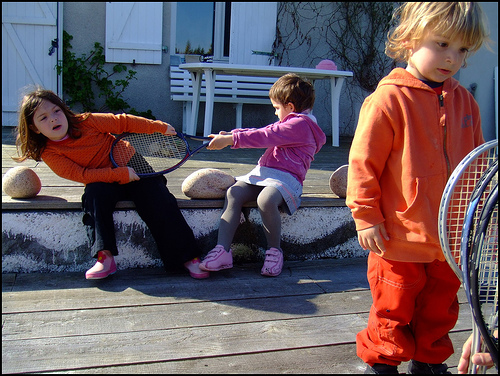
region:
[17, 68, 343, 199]
Two girls fighting over a tennis racquet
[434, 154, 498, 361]
Three tennis rackets together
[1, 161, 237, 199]
Stones spaced out on the deck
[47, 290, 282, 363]
A wooden plank walkway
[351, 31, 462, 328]
A boy in orange jacket and pants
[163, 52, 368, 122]
A white table and bench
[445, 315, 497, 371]
A hand holding a tennis racquet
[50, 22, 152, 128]
A vine growing alongside the house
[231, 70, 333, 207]
A girl with short hair in a pink jacket and skirt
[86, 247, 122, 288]
A red flower on a pink boot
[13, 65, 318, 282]
two girls fighting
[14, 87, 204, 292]
a girl in pink boots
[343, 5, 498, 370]
a boy with blonde hair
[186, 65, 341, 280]
a girl in pink sports shoes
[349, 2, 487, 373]
a boy in orange gear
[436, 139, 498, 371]
badminton rackets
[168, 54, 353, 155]
a white bench at the background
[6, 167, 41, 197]
a round stone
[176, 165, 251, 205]
a round stone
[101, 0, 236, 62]
a window at the background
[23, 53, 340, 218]
Two kids fighting over racket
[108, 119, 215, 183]
Blue and red tennis racket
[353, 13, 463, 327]
Kid wearing orange clothing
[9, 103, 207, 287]
Girl wearing orange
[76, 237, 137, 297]
Pink shoe of the girl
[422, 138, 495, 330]
Multiple tennis rackets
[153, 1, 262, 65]
Window behind kids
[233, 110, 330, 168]
Pink sweater on kid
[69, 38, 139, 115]
Green plant with many leaves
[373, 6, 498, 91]
Long hair of child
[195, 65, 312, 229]
female child pulling tennis racket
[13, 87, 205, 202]
female child holding tennis racket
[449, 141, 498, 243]
group of three tennis rackets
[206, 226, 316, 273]
girls pink sneakers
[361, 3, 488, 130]
male child looking at rackets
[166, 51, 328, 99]
patio furniture on porch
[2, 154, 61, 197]
patio rock next to child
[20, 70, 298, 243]
two females playing tug of war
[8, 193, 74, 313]
porch step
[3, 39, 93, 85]
outside porch wooden gate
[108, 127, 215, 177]
blue and red tennis racket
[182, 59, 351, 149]
white table on the porch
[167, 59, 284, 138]
white slatted bench on porch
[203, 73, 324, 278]
girl in pink tugging on tennis racket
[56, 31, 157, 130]
green viny plant near door on the wall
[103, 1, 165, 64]
window shutter that is opened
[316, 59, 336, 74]
pink tap light on table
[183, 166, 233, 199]
rock on porch between people fighting over tennis racket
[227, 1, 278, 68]
window shutter that is mostly closed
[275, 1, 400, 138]
dead looking vine plant behind boy